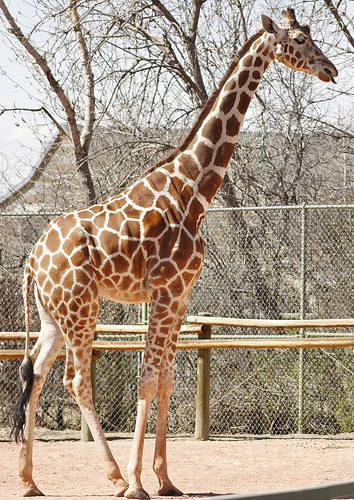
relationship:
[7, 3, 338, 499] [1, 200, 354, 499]
giraffe in enclosure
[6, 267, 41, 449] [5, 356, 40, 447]
tail has hair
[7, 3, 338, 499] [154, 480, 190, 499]
giraffe has hoof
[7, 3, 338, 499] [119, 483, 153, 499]
giraffe has hoof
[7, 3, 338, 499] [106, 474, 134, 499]
giraffe has hoof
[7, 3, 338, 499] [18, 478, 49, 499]
giraffe has hoof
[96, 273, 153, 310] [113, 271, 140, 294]
belly has spot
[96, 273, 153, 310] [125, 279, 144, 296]
belly has spot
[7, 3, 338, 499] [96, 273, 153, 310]
giraffe has belly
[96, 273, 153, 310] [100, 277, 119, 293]
belly has spot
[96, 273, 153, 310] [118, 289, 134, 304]
belly has spot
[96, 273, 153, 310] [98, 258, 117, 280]
belly has spot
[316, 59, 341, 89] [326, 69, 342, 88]
mouth has tongue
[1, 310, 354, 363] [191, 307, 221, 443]
wood on fence post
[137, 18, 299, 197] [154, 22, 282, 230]
mane on neck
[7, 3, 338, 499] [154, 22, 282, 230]
giraffe has neck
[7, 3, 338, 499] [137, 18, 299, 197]
giraffe has mane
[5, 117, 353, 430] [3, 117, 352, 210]
building has roof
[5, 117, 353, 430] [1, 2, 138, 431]
building behind tree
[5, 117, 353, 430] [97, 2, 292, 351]
building behind tree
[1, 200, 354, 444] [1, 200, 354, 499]
fence around enclosure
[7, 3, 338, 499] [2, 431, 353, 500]
giraffe on ground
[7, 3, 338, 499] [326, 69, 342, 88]
giraffe has tongue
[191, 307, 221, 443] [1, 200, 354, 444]
fence post in front of fence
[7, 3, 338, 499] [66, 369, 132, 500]
giraffe has right leg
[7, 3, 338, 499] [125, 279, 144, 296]
giraffe has spot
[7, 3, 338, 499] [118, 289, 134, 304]
giraffe has spot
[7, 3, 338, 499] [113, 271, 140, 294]
giraffe has spot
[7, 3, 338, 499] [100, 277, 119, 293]
giraffe has spot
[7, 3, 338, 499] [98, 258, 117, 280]
giraffe has spot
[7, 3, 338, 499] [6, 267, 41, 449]
giraffe has tail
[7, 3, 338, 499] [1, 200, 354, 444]
giraffe taller than fence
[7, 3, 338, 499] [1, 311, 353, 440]
giraffe taller than fence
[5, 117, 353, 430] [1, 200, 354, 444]
building behind fence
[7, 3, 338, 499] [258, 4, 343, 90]
giraffe has head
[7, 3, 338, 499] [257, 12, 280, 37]
giraffe has right ear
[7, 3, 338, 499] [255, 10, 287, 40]
giraffe has right ear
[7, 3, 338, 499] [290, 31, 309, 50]
giraffe has right eye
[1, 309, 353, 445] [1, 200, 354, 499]
fence in enclosure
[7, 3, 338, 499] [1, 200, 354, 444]
giraffe in front of fence